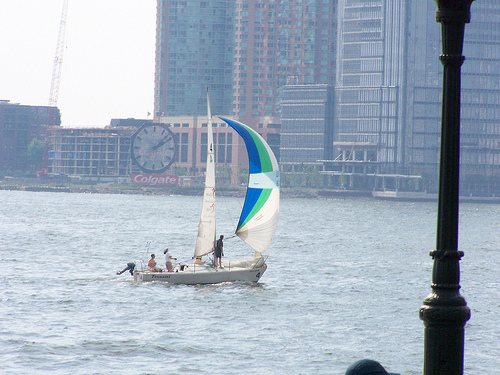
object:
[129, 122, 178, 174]
clock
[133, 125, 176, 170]
face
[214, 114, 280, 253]
sail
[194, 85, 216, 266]
sail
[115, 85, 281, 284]
sailboat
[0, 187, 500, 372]
water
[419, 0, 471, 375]
lamp post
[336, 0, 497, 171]
skyscraper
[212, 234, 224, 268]
man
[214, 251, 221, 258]
shorts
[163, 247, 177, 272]
woman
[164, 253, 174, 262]
shirt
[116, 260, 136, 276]
engine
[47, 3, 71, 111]
crane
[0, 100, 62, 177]
building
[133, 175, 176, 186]
sign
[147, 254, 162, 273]
person